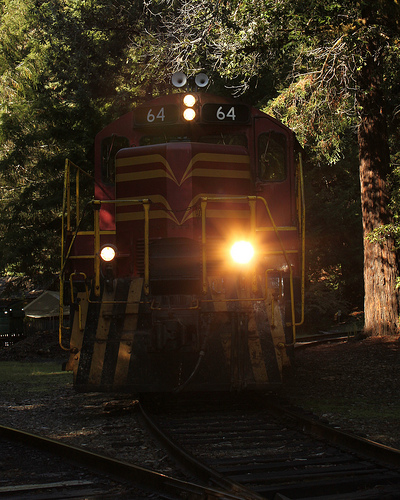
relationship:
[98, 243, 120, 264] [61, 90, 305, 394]
head lights on train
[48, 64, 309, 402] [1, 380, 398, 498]
train has railings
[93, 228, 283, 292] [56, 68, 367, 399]
head lights on train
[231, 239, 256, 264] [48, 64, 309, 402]
headlight on train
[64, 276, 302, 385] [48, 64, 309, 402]
bumper on train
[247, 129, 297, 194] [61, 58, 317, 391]
windshield on train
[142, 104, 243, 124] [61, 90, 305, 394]
en-printed numbers on train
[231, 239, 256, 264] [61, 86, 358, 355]
headlight on train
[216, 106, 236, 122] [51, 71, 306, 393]
number painted on train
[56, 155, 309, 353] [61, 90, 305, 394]
hand rail on train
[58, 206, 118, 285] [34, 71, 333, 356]
steps on train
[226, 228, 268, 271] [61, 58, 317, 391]
headlight on train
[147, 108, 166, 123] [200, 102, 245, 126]
number on black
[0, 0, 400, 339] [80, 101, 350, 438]
tree around train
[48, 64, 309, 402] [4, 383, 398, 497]
train on track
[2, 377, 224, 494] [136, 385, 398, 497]
gravel between track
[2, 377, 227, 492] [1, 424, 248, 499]
gravel between track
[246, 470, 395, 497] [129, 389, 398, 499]
plank on tracks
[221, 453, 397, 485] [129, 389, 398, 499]
plank on tracks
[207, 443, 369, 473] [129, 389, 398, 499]
plank on tracks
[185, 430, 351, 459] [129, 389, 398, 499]
plank on tracks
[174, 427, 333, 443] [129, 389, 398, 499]
plank on tracks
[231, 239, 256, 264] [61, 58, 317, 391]
headlight on train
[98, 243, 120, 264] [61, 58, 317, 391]
head lights on train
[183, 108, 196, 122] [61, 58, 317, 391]
headlight on train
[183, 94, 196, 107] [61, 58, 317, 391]
headlight on train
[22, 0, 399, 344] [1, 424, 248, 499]
tree next to track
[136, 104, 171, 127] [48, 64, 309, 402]
number on train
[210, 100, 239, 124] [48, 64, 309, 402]
number on train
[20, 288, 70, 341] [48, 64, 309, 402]
building behind train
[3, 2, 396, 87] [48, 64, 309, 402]
tops behind train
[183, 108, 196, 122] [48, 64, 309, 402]
headlight on train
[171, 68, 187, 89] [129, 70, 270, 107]
horn on top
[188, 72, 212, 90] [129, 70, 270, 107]
horn on top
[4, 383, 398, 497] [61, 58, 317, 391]
track in front of train